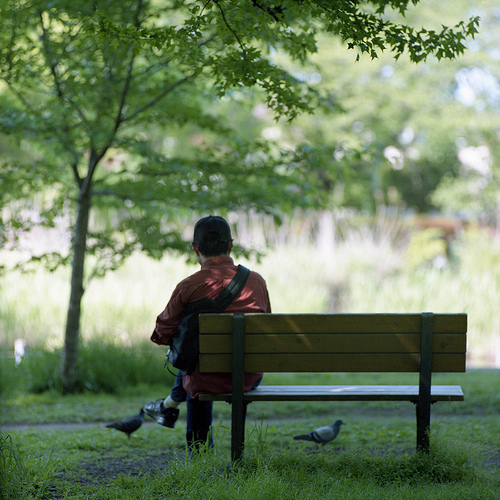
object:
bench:
[198, 312, 468, 461]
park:
[0, 0, 497, 499]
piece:
[199, 313, 467, 333]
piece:
[199, 334, 466, 354]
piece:
[199, 354, 466, 373]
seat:
[199, 385, 464, 401]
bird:
[293, 419, 345, 449]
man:
[150, 215, 270, 449]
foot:
[143, 398, 180, 428]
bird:
[105, 407, 148, 439]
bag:
[163, 264, 250, 377]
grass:
[0, 367, 499, 500]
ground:
[0, 371, 499, 499]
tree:
[0, 0, 329, 375]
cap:
[193, 215, 232, 243]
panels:
[199, 312, 466, 373]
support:
[232, 314, 246, 460]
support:
[417, 313, 432, 453]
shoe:
[143, 398, 180, 428]